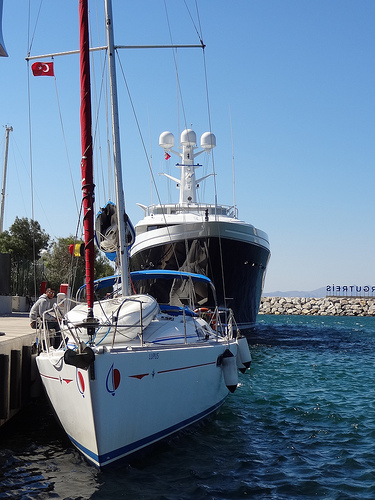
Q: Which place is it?
A: It is a harbor.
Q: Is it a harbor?
A: Yes, it is a harbor.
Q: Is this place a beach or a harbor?
A: It is a harbor.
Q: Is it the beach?
A: No, it is the harbor.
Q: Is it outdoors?
A: Yes, it is outdoors.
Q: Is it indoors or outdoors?
A: It is outdoors.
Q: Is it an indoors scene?
A: No, it is outdoors.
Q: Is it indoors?
A: No, it is outdoors.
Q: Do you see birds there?
A: No, there are no birds.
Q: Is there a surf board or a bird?
A: No, there are no birds or surfboards.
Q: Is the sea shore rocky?
A: Yes, the sea shore is rocky.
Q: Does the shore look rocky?
A: Yes, the shore is rocky.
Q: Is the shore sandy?
A: No, the shore is rocky.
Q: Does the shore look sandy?
A: No, the shore is rocky.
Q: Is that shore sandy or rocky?
A: The shore is rocky.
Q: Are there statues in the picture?
A: No, there are no statues.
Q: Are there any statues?
A: No, there are no statues.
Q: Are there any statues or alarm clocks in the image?
A: No, there are no statues or alarm clocks.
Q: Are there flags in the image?
A: Yes, there is a flag.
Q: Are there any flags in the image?
A: Yes, there is a flag.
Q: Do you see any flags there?
A: Yes, there is a flag.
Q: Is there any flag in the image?
A: Yes, there is a flag.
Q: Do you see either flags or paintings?
A: Yes, there is a flag.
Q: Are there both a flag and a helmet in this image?
A: No, there is a flag but no helmets.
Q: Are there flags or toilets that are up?
A: Yes, the flag is up.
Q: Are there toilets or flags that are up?
A: Yes, the flag is up.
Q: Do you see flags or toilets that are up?
A: Yes, the flag is up.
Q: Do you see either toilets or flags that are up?
A: Yes, the flag is up.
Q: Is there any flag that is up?
A: Yes, there is a flag that is up.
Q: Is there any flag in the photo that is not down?
A: Yes, there is a flag that is up.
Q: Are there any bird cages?
A: No, there are no bird cages.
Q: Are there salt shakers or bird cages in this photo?
A: No, there are no bird cages or salt shakers.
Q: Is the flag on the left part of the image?
A: Yes, the flag is on the left of the image.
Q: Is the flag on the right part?
A: No, the flag is on the left of the image.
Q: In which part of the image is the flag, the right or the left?
A: The flag is on the left of the image.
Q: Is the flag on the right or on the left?
A: The flag is on the left of the image.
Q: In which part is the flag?
A: The flag is on the left of the image.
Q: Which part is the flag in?
A: The flag is on the left of the image.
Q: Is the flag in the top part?
A: Yes, the flag is in the top of the image.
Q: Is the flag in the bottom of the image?
A: No, the flag is in the top of the image.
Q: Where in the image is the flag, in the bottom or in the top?
A: The flag is in the top of the image.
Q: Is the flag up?
A: Yes, the flag is up.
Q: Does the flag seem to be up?
A: Yes, the flag is up.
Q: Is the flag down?
A: No, the flag is up.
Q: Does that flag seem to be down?
A: No, the flag is up.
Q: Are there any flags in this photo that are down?
A: No, there is a flag but it is up.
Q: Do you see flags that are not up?
A: No, there is a flag but it is up.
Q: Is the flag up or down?
A: The flag is up.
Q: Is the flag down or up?
A: The flag is up.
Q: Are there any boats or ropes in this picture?
A: Yes, there is a boat.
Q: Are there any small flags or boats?
A: Yes, there is a small boat.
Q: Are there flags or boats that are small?
A: Yes, the boat is small.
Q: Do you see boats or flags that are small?
A: Yes, the boat is small.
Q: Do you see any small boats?
A: Yes, there is a small boat.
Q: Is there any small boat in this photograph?
A: Yes, there is a small boat.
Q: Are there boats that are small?
A: Yes, there is a boat that is small.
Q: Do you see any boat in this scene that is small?
A: Yes, there is a boat that is small.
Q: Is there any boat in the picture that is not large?
A: Yes, there is a small boat.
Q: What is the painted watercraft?
A: The watercraft is a boat.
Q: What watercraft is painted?
A: The watercraft is a boat.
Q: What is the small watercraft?
A: The watercraft is a boat.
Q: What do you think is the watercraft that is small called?
A: The watercraft is a boat.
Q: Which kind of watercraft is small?
A: The watercraft is a boat.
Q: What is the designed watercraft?
A: The watercraft is a boat.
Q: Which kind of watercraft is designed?
A: The watercraft is a boat.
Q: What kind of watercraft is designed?
A: The watercraft is a boat.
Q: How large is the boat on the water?
A: The boat is small.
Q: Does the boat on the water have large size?
A: No, the boat is small.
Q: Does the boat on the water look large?
A: No, the boat is small.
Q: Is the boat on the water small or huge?
A: The boat is small.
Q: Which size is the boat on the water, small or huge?
A: The boat is small.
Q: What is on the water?
A: The boat is on the water.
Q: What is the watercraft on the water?
A: The watercraft is a boat.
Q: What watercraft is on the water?
A: The watercraft is a boat.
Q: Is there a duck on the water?
A: No, there is a boat on the water.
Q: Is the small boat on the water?
A: Yes, the boat is on the water.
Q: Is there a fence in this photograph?
A: No, there are no fences.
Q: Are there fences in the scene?
A: No, there are no fences.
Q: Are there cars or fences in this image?
A: No, there are no fences or cars.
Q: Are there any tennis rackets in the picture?
A: No, there are no tennis rackets.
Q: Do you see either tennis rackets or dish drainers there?
A: No, there are no tennis rackets or dish drainers.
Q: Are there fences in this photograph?
A: No, there are no fences.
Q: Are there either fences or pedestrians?
A: No, there are no fences or pedestrians.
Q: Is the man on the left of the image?
A: Yes, the man is on the left of the image.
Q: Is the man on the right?
A: No, the man is on the left of the image.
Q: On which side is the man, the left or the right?
A: The man is on the left of the image.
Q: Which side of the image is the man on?
A: The man is on the left of the image.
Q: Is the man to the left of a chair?
A: No, the man is to the left of the boat.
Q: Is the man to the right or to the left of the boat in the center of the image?
A: The man is to the left of the boat.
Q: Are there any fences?
A: No, there are no fences.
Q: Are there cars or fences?
A: No, there are no fences or cars.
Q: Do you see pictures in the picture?
A: No, there are no pictures.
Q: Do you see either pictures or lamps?
A: No, there are no pictures or lamps.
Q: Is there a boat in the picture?
A: Yes, there is a boat.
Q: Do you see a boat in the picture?
A: Yes, there is a boat.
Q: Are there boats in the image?
A: Yes, there is a boat.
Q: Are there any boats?
A: Yes, there is a boat.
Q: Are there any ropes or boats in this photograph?
A: Yes, there is a boat.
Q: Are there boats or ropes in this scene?
A: Yes, there is a boat.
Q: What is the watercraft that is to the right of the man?
A: The watercraft is a boat.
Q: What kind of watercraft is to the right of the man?
A: The watercraft is a boat.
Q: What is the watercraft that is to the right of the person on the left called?
A: The watercraft is a boat.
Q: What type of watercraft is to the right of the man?
A: The watercraft is a boat.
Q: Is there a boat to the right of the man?
A: Yes, there is a boat to the right of the man.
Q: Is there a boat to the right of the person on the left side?
A: Yes, there is a boat to the right of the man.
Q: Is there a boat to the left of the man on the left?
A: No, the boat is to the right of the man.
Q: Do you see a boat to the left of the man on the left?
A: No, the boat is to the right of the man.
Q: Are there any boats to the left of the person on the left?
A: No, the boat is to the right of the man.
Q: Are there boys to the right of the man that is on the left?
A: No, there is a boat to the right of the man.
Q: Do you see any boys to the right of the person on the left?
A: No, there is a boat to the right of the man.